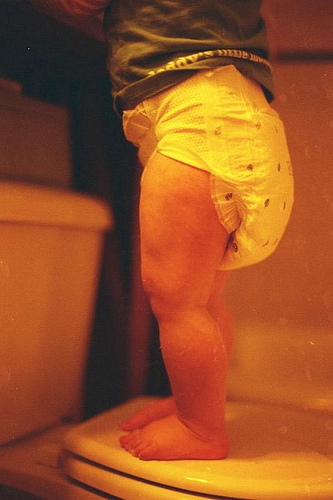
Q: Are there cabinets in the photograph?
A: No, there are no cabinets.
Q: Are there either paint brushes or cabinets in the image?
A: No, there are no cabinets or paint brushes.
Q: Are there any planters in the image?
A: No, there are no planters.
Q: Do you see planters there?
A: No, there are no planters.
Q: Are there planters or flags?
A: No, there are no planters or flags.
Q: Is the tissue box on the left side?
A: Yes, the tissue box is on the left of the image.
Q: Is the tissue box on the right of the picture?
A: No, the tissue box is on the left of the image.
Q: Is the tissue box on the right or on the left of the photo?
A: The tissue box is on the left of the image.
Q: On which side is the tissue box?
A: The tissue box is on the left of the image.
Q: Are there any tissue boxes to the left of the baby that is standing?
A: Yes, there is a tissue box to the left of the baby.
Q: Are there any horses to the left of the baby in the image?
A: No, there is a tissue box to the left of the baby.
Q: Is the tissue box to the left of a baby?
A: Yes, the tissue box is to the left of a baby.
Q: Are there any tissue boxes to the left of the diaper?
A: Yes, there is a tissue box to the left of the diaper.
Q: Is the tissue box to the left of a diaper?
A: Yes, the tissue box is to the left of a diaper.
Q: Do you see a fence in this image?
A: No, there are no fences.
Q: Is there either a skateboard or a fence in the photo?
A: No, there are no fences or skateboards.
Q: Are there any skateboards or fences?
A: No, there are no fences or skateboards.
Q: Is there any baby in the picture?
A: Yes, there is a baby.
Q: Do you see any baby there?
A: Yes, there is a baby.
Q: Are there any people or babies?
A: Yes, there is a baby.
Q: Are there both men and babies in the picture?
A: No, there is a baby but no men.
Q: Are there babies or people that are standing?
A: Yes, the baby is standing.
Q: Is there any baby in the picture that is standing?
A: Yes, there is a baby that is standing.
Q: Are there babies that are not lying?
A: Yes, there is a baby that is standing.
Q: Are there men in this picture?
A: No, there are no men.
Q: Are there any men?
A: No, there are no men.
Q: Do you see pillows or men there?
A: No, there are no men or pillows.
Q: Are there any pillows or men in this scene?
A: No, there are no men or pillows.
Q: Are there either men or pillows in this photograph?
A: No, there are no men or pillows.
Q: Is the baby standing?
A: Yes, the baby is standing.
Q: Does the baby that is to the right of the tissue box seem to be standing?
A: Yes, the baby is standing.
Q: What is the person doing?
A: The baby is standing.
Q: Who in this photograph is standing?
A: The baby is standing.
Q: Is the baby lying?
A: No, the baby is standing.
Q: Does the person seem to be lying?
A: No, the baby is standing.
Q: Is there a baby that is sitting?
A: No, there is a baby but he is standing.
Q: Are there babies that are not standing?
A: No, there is a baby but he is standing.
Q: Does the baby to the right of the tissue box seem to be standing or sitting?
A: The baby is standing.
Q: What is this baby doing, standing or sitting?
A: The baby is standing.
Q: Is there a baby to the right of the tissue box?
A: Yes, there is a baby to the right of the tissue box.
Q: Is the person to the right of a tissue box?
A: Yes, the baby is to the right of a tissue box.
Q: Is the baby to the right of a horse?
A: No, the baby is to the right of a tissue box.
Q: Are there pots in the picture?
A: No, there are no pots.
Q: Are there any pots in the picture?
A: No, there are no pots.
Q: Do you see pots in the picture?
A: No, there are no pots.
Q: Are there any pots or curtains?
A: No, there are no pots or curtains.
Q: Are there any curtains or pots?
A: No, there are no pots or curtains.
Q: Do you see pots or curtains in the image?
A: No, there are no pots or curtains.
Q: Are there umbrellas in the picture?
A: No, there are no umbrellas.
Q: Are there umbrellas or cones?
A: No, there are no umbrellas or cones.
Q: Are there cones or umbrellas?
A: No, there are no umbrellas or cones.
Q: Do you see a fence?
A: No, there are no fences.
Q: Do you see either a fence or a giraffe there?
A: No, there are no fences or giraffes.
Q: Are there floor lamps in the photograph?
A: No, there are no floor lamps.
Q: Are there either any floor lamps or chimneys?
A: No, there are no floor lamps or chimneys.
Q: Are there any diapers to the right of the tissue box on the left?
A: Yes, there is a diaper to the right of the tissue box.